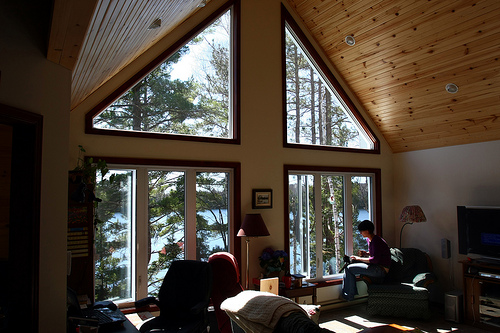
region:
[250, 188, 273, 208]
picture on wall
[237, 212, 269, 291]
lamp in living room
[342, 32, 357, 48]
recessed light in ceiling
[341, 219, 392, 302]
person sitting on arm of chair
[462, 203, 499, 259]
flat screen tv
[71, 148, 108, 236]
plant in the window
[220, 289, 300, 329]
blanket on the back of a chair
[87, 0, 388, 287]
large windows on wall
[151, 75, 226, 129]
trees outside of window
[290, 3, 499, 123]
wooden ceiling in room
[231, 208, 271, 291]
tall lamp against the wall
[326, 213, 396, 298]
person sitting on the edge of the chair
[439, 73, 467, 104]
light in the ceiling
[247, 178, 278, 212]
picture on the wall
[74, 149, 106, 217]
green plant on top of the shelf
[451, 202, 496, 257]
TV on a stand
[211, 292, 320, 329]
blanket laying on top of the chair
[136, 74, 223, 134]
trees out the window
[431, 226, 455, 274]
speaker attached to the wall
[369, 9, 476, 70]
wood plank ceiling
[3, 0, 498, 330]
living room with large windows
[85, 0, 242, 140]
triangular left window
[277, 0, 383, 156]
triangular right window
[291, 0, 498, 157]
wooden paneled ceiling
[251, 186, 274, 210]
small framed print on wall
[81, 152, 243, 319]
rectangular living room windows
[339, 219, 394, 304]
person sitting on arm of a chair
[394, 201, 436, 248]
floor lamp with patterned shade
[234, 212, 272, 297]
floor lamp with reddish-brown shade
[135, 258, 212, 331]
black office chair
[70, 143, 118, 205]
A green house plant.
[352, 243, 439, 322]
A armchair.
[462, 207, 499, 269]
A flatscreen television.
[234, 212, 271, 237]
A dark colored lamp shade.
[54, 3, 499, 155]
A wooden ceiling.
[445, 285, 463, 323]
A silver speaker.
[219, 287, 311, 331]
A beige folded blanket.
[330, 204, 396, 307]
A person sitting by the window on the arm of a chair.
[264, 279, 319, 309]
A small table.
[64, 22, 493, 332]
The living room of a house.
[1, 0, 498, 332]
room with vaulted ceiling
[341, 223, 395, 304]
a woman sitting on arm of chair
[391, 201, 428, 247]
a curved floor lamp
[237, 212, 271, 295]
a straight floor lamp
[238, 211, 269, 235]
burgandy lamp shade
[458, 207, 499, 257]
a flat screen television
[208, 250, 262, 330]
a red recliner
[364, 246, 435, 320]
a dark green and dotted sofa chair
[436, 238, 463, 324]
a set of speakers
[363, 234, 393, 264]
a purple long sleeve shirt